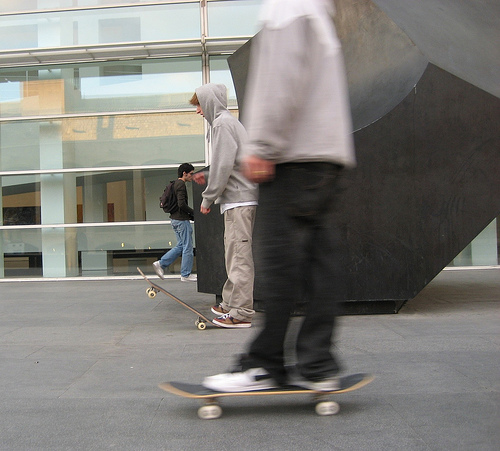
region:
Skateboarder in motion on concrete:
[155, 7, 378, 422]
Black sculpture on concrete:
[193, 1, 498, 316]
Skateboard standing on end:
[132, 262, 213, 331]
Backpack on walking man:
[157, 179, 178, 213]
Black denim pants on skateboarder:
[237, 161, 346, 378]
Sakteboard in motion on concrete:
[157, 373, 381, 420]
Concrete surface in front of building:
[4, 267, 499, 448]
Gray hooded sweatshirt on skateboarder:
[195, 79, 255, 206]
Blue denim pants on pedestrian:
[157, 221, 194, 274]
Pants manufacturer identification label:
[236, 235, 250, 246]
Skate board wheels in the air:
[146, 288, 155, 297]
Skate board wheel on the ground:
[198, 322, 205, 328]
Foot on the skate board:
[215, 317, 222, 323]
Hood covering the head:
[200, 87, 220, 102]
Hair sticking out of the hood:
[192, 97, 197, 102]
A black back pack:
[164, 191, 172, 208]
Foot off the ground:
[154, 262, 159, 274]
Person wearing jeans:
[182, 227, 187, 238]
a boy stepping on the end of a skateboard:
[132, 91, 262, 324]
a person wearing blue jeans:
[164, 216, 197, 274]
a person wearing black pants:
[247, 168, 359, 360]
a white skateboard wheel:
[202, 408, 222, 420]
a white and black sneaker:
[208, 366, 281, 396]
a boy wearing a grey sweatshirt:
[189, 83, 261, 208]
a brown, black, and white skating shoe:
[212, 308, 252, 330]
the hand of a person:
[243, 149, 272, 181]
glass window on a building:
[27, 65, 202, 113]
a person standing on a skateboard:
[150, 318, 372, 428]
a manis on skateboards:
[228, 31, 409, 414]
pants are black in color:
[251, 182, 339, 383]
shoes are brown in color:
[212, 297, 257, 334]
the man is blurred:
[258, 20, 331, 383]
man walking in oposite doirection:
[150, 151, 208, 272]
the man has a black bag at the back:
[151, 182, 203, 239]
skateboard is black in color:
[151, 370, 378, 427]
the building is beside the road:
[47, 88, 182, 263]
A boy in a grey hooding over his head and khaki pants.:
[188, 84, 256, 328]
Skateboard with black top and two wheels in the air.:
[134, 266, 221, 327]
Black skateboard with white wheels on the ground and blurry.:
[156, 372, 381, 417]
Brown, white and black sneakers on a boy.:
[208, 304, 251, 327]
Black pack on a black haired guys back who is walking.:
[156, 181, 177, 216]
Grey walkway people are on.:
[1, 274, 499, 449]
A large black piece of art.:
[191, 0, 498, 315]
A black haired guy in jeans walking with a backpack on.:
[154, 162, 199, 282]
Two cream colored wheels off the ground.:
[144, 287, 157, 299]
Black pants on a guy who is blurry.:
[231, 163, 341, 379]